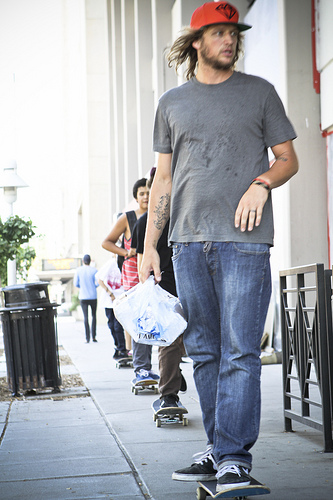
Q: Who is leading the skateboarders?
A: A man in an red cap.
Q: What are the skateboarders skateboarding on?
A: A concrete sidewalk in the city.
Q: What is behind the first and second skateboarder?
A: A small black iron fence.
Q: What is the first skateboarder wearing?
A: A grey shirt and jeans.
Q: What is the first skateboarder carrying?
A: A plastic grocery bag.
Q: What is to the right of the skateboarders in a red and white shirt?
A: A garbage can.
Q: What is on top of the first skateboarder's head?
A: A red cap.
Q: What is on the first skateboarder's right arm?
A: A tattoo.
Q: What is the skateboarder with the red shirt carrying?
A: A backpack.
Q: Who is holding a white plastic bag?
A: Man on skateboard.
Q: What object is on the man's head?
A: Orange baseball cap.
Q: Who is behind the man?
A: Three people on skateboards.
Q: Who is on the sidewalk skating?
A: A man.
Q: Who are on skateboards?
A: A line of men.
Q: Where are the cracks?
A: The sidewalk.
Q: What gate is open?
A: The metal gate.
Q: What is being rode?
A: Skateboards.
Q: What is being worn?
A: A gray t-shirt.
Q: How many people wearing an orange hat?
A: One.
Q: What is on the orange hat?
A: Diamond design.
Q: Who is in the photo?
A: A man.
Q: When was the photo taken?
A: Day time.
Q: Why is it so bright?
A: Sunny.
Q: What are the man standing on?
A: A skateboard.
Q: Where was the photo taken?
A: On a street.